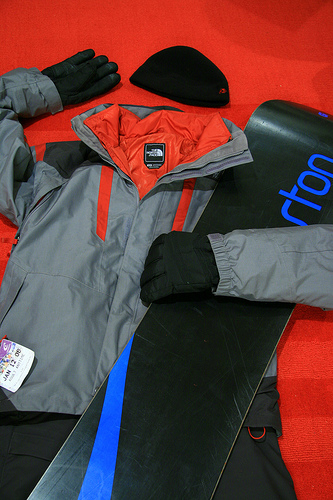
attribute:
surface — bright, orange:
[0, 0, 331, 494]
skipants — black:
[104, 296, 302, 498]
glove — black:
[137, 231, 219, 307]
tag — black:
[143, 142, 164, 169]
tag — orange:
[249, 416, 276, 443]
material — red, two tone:
[1, 0, 332, 498]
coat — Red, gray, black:
[3, 44, 320, 498]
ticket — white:
[0, 334, 36, 395]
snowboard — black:
[73, 98, 330, 498]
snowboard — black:
[22, 64, 326, 498]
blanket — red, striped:
[289, 342, 330, 405]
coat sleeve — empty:
[153, 228, 332, 296]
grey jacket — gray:
[0, 65, 331, 430]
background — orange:
[19, 16, 331, 342]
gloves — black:
[45, 40, 220, 306]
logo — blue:
[272, 149, 318, 203]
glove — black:
[136, 226, 216, 307]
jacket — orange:
[132, 119, 195, 142]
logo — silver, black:
[139, 143, 170, 178]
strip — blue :
[74, 327, 141, 498]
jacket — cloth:
[0, 56, 322, 431]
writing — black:
[4, 347, 25, 378]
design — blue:
[85, 358, 131, 474]